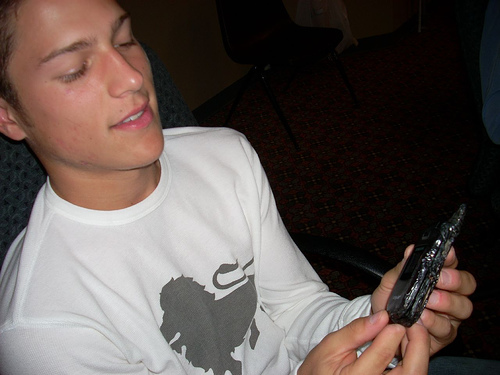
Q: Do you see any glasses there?
A: No, there are no glasses.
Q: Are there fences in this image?
A: No, there are no fences.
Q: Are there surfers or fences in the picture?
A: No, there are no fences or surfers.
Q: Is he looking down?
A: Yes, the boy is looking down.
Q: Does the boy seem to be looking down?
A: Yes, the boy is looking down.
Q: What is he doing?
A: The boy is looking down.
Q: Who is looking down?
A: The boy is looking down.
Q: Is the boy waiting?
A: No, the boy is looking down.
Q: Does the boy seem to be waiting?
A: No, the boy is looking down.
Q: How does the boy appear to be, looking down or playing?
A: The boy is looking down.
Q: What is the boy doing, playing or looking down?
A: The boy is looking down.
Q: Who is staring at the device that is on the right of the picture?
A: The boy is staring at the phone.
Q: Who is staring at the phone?
A: The boy is staring at the phone.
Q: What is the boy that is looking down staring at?
A: The boy is staring at the telephone.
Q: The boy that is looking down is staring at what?
A: The boy is staring at the telephone.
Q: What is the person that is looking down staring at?
A: The boy is staring at the telephone.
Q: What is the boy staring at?
A: The boy is staring at the telephone.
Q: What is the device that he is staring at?
A: The device is a phone.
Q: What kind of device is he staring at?
A: The boy is staring at the telephone.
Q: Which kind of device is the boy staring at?
A: The boy is staring at the telephone.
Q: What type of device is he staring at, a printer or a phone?
A: The boy is staring at a phone.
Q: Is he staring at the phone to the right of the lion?
A: Yes, the boy is staring at the telephone.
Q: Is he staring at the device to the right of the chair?
A: Yes, the boy is staring at the telephone.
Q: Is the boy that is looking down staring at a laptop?
A: No, the boy is staring at the telephone.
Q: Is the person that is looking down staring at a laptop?
A: No, the boy is staring at the telephone.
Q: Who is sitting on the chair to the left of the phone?
A: The boy is sitting on the chair.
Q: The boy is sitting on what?
A: The boy is sitting on the chair.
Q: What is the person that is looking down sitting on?
A: The boy is sitting on the chair.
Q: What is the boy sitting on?
A: The boy is sitting on the chair.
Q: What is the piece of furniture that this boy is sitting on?
A: The piece of furniture is a chair.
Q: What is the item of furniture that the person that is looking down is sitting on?
A: The piece of furniture is a chair.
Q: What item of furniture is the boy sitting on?
A: The boy is sitting on the chair.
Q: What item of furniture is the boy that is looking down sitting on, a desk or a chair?
A: The boy is sitting on a chair.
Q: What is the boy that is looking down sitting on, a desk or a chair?
A: The boy is sitting on a chair.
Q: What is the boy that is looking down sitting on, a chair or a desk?
A: The boy is sitting on a chair.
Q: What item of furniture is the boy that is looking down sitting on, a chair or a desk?
A: The boy is sitting on a chair.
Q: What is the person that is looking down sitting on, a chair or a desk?
A: The boy is sitting on a chair.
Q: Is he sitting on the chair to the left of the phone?
A: Yes, the boy is sitting on the chair.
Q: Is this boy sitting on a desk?
A: No, the boy is sitting on the chair.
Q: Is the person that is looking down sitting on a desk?
A: No, the boy is sitting on the chair.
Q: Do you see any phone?
A: Yes, there is a phone.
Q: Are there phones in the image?
A: Yes, there is a phone.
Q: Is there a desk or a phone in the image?
A: Yes, there is a phone.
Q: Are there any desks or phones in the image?
A: Yes, there is a phone.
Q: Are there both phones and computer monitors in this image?
A: No, there is a phone but no computer monitors.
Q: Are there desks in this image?
A: No, there are no desks.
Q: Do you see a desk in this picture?
A: No, there are no desks.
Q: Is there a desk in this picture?
A: No, there are no desks.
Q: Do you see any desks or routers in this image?
A: No, there are no desks or routers.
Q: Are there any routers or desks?
A: No, there are no desks or routers.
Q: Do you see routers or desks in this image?
A: No, there are no desks or routers.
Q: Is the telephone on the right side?
A: Yes, the telephone is on the right of the image.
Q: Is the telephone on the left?
A: No, the telephone is on the right of the image.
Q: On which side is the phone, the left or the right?
A: The phone is on the right of the image.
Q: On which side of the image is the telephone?
A: The telephone is on the right of the image.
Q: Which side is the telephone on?
A: The telephone is on the right of the image.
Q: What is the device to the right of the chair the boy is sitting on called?
A: The device is a phone.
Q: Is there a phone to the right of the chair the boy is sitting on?
A: Yes, there is a phone to the right of the chair.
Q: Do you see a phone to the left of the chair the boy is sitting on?
A: No, the phone is to the right of the chair.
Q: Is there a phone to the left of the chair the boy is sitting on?
A: No, the phone is to the right of the chair.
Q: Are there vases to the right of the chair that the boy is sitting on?
A: No, there is a phone to the right of the chair.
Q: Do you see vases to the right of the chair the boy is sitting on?
A: No, there is a phone to the right of the chair.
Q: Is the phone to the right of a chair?
A: Yes, the phone is to the right of a chair.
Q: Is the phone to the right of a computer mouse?
A: No, the phone is to the right of a chair.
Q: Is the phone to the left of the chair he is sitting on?
A: No, the phone is to the right of the chair.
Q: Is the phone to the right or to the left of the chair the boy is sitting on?
A: The phone is to the right of the chair.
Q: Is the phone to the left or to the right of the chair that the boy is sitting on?
A: The phone is to the right of the chair.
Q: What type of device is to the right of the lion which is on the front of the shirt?
A: The device is a phone.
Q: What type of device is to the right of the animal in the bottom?
A: The device is a phone.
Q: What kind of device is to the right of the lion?
A: The device is a phone.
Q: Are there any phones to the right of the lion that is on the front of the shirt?
A: Yes, there is a phone to the right of the lion.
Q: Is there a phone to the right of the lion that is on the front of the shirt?
A: Yes, there is a phone to the right of the lion.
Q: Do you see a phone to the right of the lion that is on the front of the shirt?
A: Yes, there is a phone to the right of the lion.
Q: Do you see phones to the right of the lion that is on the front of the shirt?
A: Yes, there is a phone to the right of the lion.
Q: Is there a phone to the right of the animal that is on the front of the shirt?
A: Yes, there is a phone to the right of the lion.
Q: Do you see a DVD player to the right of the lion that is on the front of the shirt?
A: No, there is a phone to the right of the lion.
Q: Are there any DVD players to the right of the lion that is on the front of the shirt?
A: No, there is a phone to the right of the lion.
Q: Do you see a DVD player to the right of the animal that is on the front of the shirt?
A: No, there is a phone to the right of the lion.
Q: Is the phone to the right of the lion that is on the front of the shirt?
A: Yes, the phone is to the right of the lion.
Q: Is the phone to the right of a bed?
A: No, the phone is to the right of the lion.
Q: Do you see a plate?
A: No, there are no plates.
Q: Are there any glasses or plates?
A: No, there are no plates or glasses.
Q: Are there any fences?
A: No, there are no fences.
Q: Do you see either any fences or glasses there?
A: No, there are no fences or glasses.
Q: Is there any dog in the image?
A: No, there are no dogs.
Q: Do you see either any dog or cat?
A: No, there are no dogs or cats.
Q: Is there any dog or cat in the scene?
A: No, there are no dogs or cats.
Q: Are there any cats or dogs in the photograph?
A: No, there are no dogs or cats.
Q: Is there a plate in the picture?
A: No, there are no plates.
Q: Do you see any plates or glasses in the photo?
A: No, there are no plates or glasses.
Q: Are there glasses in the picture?
A: No, there are no glasses.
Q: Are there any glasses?
A: No, there are no glasses.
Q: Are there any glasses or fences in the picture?
A: No, there are no glasses or fences.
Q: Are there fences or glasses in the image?
A: No, there are no glasses or fences.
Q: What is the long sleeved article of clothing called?
A: The clothing item is a shirt.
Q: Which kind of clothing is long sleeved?
A: The clothing is a shirt.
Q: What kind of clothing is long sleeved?
A: The clothing is a shirt.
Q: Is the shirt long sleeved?
A: Yes, the shirt is long sleeved.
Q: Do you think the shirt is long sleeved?
A: Yes, the shirt is long sleeved.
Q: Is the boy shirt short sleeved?
A: No, the shirt is long sleeved.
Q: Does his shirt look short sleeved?
A: No, the shirt is long sleeved.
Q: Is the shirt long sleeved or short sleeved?
A: The shirt is long sleeved.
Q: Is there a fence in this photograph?
A: No, there are no fences.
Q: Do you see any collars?
A: Yes, there is a collar.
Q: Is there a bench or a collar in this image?
A: Yes, there is a collar.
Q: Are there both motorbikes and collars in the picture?
A: No, there is a collar but no motorcycles.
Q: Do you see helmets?
A: No, there are no helmets.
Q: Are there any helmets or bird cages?
A: No, there are no helmets or bird cages.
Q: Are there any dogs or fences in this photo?
A: No, there are no dogs or fences.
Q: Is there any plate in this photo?
A: No, there are no plates.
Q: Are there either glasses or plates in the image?
A: No, there are no plates or glasses.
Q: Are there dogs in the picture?
A: No, there are no dogs.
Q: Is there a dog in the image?
A: No, there are no dogs.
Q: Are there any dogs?
A: No, there are no dogs.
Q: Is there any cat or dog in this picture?
A: No, there are no dogs or cats.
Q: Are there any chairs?
A: Yes, there is a chair.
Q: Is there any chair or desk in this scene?
A: Yes, there is a chair.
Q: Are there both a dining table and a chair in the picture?
A: No, there is a chair but no dining tables.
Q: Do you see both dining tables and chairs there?
A: No, there is a chair but no dining tables.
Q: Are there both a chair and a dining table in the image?
A: No, there is a chair but no dining tables.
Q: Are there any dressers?
A: No, there are no dressers.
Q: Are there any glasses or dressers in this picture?
A: No, there are no dressers or glasses.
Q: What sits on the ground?
A: The chair sits on the ground.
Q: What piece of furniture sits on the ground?
A: The piece of furniture is a chair.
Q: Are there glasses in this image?
A: No, there are no glasses.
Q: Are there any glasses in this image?
A: No, there are no glasses.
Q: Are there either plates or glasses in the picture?
A: No, there are no glasses or plates.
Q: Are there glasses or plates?
A: No, there are no glasses or plates.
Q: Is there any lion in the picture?
A: Yes, there is a lion.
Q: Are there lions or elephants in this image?
A: Yes, there is a lion.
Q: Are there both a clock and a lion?
A: No, there is a lion but no clocks.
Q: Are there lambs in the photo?
A: No, there are no lambs.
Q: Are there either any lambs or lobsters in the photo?
A: No, there are no lambs or lobsters.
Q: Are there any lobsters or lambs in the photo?
A: No, there are no lambs or lobsters.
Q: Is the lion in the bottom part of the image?
A: Yes, the lion is in the bottom of the image.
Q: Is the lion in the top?
A: No, the lion is in the bottom of the image.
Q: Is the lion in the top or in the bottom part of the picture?
A: The lion is in the bottom of the image.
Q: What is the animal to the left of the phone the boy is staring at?
A: The animal is a lion.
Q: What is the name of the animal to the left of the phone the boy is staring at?
A: The animal is a lion.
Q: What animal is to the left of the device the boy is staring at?
A: The animal is a lion.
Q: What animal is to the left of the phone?
A: The animal is a lion.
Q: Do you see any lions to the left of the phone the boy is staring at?
A: Yes, there is a lion to the left of the telephone.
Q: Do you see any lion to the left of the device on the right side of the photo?
A: Yes, there is a lion to the left of the telephone.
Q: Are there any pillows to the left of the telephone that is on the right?
A: No, there is a lion to the left of the phone.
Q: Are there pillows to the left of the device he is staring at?
A: No, there is a lion to the left of the phone.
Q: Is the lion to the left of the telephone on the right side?
A: Yes, the lion is to the left of the telephone.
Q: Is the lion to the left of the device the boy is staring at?
A: Yes, the lion is to the left of the telephone.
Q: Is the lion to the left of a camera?
A: No, the lion is to the left of the telephone.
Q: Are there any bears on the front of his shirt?
A: No, there is a lion on the front of the shirt.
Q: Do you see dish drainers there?
A: No, there are no dish drainers.